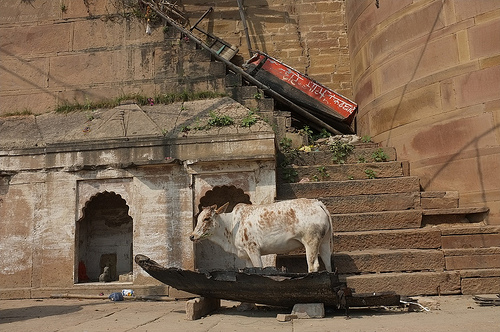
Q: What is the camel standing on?
A: A piece of broken stone.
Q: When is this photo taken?
A: During the day.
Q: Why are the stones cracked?
A: Looks like an old location.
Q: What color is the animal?
A: Brown and white.